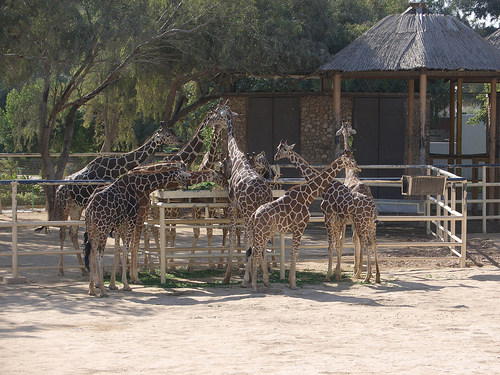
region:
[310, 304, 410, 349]
the floor is coverd wuth sand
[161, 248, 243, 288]
the floor has green plants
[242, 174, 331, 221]
the giraffes are grouped togther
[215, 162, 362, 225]
giraffes are brown and white in color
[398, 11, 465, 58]
the roof is grass tacthed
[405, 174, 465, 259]
the fence is white in color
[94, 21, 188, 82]
plants are green in color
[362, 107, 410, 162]
the door is wooden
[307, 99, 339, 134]
the wall is made of rocks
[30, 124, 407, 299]
giraffes in the enclosure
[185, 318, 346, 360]
sand on the ground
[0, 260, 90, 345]
shadows on the ground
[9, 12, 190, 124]
trees on the left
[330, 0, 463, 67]
roof of the house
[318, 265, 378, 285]
feet of the giraffe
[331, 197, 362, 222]
spots on the giraffe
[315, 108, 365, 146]
head of the giraffe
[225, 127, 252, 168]
neck of the giraffe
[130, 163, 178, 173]
mane of the giraffe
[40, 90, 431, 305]
there are giraffes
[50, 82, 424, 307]
a pack of giraffes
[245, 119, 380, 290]
these giraffes are younger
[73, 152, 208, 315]
the giraffe is drinking water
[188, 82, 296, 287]
this giraffe is feeding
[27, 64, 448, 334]
the giraffes are surrounding a fence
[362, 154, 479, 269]
this is part of an iron fence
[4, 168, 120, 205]
some of the paint on the fence is chipped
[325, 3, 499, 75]
a thatched roof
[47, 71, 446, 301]
these are giraffes at a zoo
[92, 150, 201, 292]
A brown white giraffe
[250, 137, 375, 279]
A brown white giraffe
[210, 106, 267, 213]
A brown white giraffe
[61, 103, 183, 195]
A brown white giraffe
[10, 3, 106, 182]
A tall green tree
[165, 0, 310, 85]
A tall green tree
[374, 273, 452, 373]
A brown sand ground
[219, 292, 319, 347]
A brown sand ground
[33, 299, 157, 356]
A brown sand ground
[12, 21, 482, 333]
giraffes in a pen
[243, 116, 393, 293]
giraffes are medium size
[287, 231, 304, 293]
front legs of giraffe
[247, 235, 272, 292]
back legs of giraffe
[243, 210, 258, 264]
the tail is long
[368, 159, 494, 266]
fence is made of wood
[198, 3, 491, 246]
a cabin behind a fence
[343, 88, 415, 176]
door of cabin is brown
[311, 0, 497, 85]
roof of cabin is made of straw